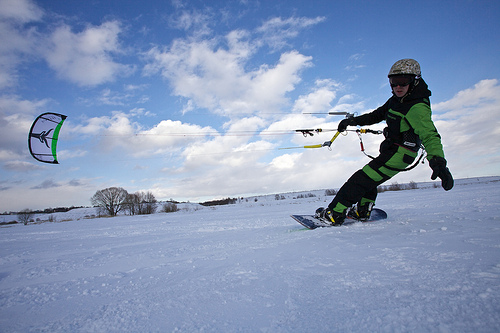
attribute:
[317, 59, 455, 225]
person — holding, riding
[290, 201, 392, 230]
snowboard — dark, black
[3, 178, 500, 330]
snow — white, covering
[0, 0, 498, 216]
sky — blue, white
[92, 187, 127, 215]
tree — bare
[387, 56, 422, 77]
helmet — brown, spotted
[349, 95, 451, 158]
jacket — green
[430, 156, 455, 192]
glove — black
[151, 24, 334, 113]
clouds — fluffy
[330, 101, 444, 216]
outfit — green, black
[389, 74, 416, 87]
goggles — black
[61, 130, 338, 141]
strings — clear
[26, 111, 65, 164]
parasail — black, flying